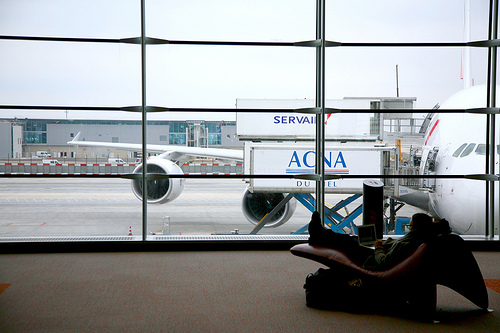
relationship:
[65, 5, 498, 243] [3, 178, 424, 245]
plane on pavement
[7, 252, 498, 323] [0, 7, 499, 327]
carpeting in room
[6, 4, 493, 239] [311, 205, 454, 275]
windows in front of person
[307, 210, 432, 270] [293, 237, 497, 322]
person laying on cushion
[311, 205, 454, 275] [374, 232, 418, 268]
person wearing shirt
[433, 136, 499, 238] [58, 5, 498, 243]
front of plane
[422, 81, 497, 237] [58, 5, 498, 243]
body of plane